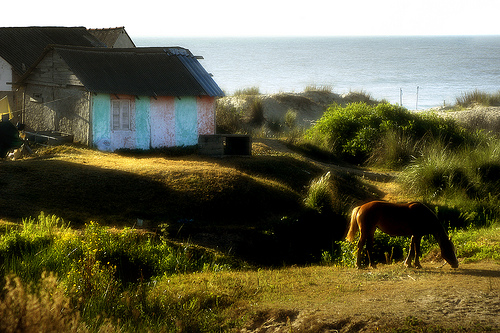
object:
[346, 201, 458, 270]
horse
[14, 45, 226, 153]
house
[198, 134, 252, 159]
stall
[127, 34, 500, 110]
water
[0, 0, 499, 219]
background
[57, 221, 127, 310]
flowers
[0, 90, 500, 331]
field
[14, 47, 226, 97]
roof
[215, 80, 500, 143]
sand dune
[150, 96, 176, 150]
stripe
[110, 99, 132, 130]
window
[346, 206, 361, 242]
tail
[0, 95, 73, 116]
wire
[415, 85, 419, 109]
pole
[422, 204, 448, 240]
mane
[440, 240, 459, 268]
head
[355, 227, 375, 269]
leg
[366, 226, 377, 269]
leg